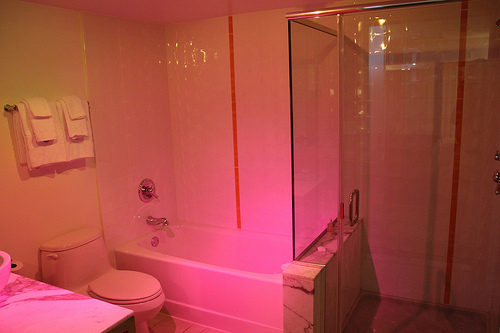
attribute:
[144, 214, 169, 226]
bath faucet — silver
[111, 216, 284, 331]
tub — full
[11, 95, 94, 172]
towels — white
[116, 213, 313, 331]
bathtub — white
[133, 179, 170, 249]
fixtures — silver, for tub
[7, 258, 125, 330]
sink — Marble 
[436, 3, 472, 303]
stripe — orange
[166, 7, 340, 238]
wall — tiles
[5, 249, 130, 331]
sink — granite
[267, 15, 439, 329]
wall — separating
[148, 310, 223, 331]
floor — tiles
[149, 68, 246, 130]
tiles — white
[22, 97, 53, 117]
wash cloth — hanging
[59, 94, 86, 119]
wash cloth — hanging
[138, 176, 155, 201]
handle — Stainless steel , shower's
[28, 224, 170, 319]
toliet — Pink 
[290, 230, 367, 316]
marble wall — dividing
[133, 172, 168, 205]
shower handle — silver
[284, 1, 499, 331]
shower stall — glass, clear